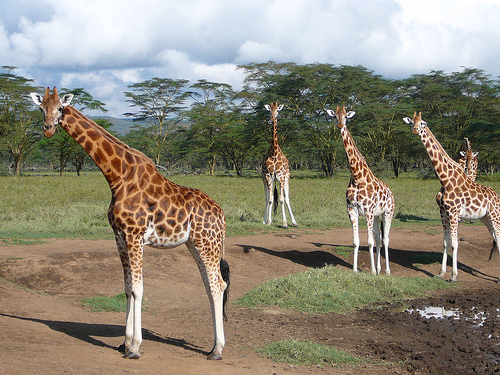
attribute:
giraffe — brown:
[27, 68, 253, 368]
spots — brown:
[267, 157, 290, 186]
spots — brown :
[127, 181, 166, 226]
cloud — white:
[369, 7, 478, 67]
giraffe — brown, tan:
[259, 100, 301, 229]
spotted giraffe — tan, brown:
[407, 104, 499, 286]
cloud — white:
[6, 1, 353, 70]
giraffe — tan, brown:
[451, 131, 481, 186]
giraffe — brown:
[405, 108, 496, 298]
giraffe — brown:
[252, 92, 302, 247]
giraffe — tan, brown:
[398, 105, 498, 282]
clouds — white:
[23, 6, 491, 74]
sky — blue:
[72, 10, 304, 46]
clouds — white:
[4, 1, 498, 106]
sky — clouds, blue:
[4, 1, 499, 113]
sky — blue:
[3, 4, 498, 61]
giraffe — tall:
[409, 112, 499, 269]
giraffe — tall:
[327, 105, 394, 264]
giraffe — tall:
[258, 107, 290, 224]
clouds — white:
[0, 6, 177, 68]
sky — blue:
[1, 0, 496, 57]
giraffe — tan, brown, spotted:
[10, 55, 260, 366]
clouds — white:
[11, 5, 483, 118]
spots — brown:
[146, 208, 183, 236]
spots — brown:
[452, 185, 479, 211]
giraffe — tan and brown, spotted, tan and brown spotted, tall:
[27, 84, 227, 362]